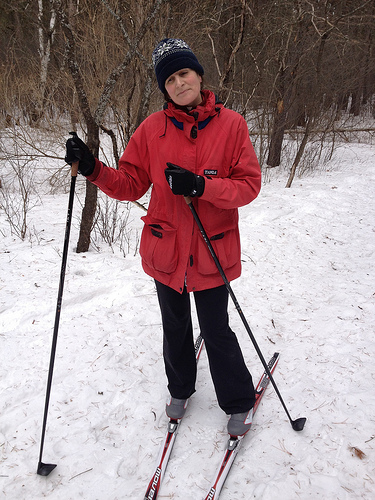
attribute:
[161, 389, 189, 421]
boot — gray, red, white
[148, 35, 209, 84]
wool hat — white, blue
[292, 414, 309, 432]
disc support — black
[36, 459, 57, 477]
disc support — black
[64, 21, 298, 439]
woman' — black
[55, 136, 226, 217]
gloves — black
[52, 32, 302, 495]
skiier — female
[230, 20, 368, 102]
tree — assortment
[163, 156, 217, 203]
glove — black, big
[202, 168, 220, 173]
logo — black, white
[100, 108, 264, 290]
coat — red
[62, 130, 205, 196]
glove — big, black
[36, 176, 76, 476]
pole — tall, black, ski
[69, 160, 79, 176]
handle — brown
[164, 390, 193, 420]
ski boot — gray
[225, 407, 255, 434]
ski boot — gray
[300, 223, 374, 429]
snow — thin covering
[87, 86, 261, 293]
jacket — red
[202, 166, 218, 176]
patch — black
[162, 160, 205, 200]
glove — black, big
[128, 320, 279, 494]
skis — white, red, black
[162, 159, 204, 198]
snow glove — black, big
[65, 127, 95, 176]
snow glove — big, black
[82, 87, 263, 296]
coat — well insulated, thick, red, ski coat, women's coat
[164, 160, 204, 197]
glove — big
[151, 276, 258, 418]
pants — warm, black, ski pants, ski